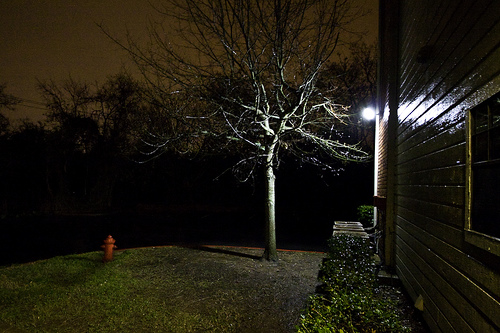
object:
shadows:
[0, 143, 363, 257]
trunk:
[262, 158, 278, 264]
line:
[112, 244, 327, 254]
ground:
[0, 244, 433, 333]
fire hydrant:
[100, 235, 117, 263]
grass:
[1, 243, 328, 333]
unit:
[333, 231, 369, 239]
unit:
[334, 221, 363, 227]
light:
[361, 105, 378, 122]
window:
[465, 92, 499, 239]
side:
[373, 0, 493, 331]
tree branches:
[77, 0, 374, 184]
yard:
[0, 196, 440, 333]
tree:
[90, 0, 371, 267]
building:
[371, 0, 500, 333]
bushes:
[299, 221, 414, 333]